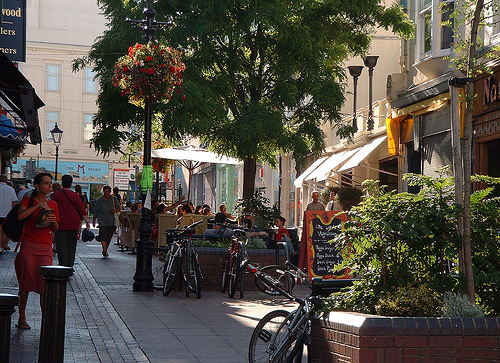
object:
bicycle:
[246, 294, 324, 363]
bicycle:
[219, 229, 251, 299]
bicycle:
[237, 238, 296, 298]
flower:
[135, 44, 142, 50]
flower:
[147, 68, 154, 75]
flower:
[146, 55, 153, 62]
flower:
[151, 45, 158, 49]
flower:
[176, 67, 182, 72]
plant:
[111, 42, 187, 109]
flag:
[385, 113, 413, 156]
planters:
[162, 246, 290, 292]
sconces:
[362, 56, 380, 133]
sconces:
[347, 65, 365, 132]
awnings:
[324, 147, 362, 175]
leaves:
[359, 178, 391, 196]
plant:
[313, 163, 461, 317]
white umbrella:
[151, 141, 244, 174]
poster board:
[305, 210, 356, 283]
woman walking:
[13, 250, 64, 314]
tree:
[408, 0, 499, 304]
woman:
[177, 205, 192, 224]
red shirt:
[19, 195, 60, 245]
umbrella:
[132, 143, 245, 165]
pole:
[177, 159, 206, 205]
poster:
[140, 165, 154, 194]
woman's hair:
[31, 173, 53, 199]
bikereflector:
[252, 268, 258, 273]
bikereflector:
[185, 230, 195, 237]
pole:
[53, 143, 61, 182]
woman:
[175, 205, 187, 220]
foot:
[14, 320, 31, 329]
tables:
[152, 213, 222, 233]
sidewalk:
[2, 222, 325, 361]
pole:
[131, 0, 156, 291]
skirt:
[14, 239, 52, 294]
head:
[33, 173, 54, 194]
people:
[271, 217, 300, 261]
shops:
[291, 65, 499, 221]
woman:
[13, 172, 60, 329]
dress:
[13, 195, 60, 294]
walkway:
[71, 260, 102, 361]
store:
[303, 123, 410, 232]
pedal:
[257, 329, 272, 343]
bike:
[150, 220, 208, 299]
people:
[203, 212, 234, 236]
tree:
[70, 0, 418, 220]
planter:
[305, 307, 500, 363]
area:
[1, 208, 484, 358]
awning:
[293, 156, 330, 188]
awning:
[304, 149, 347, 181]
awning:
[316, 149, 357, 183]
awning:
[336, 135, 387, 173]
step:
[168, 240, 294, 293]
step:
[302, 301, 482, 360]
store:
[384, 85, 470, 235]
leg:
[39, 259, 52, 310]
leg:
[19, 260, 32, 317]